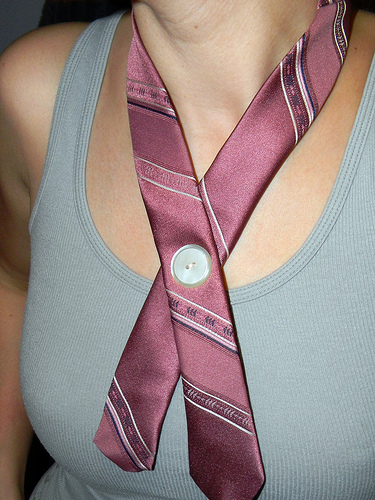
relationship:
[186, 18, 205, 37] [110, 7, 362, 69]
freckle on neck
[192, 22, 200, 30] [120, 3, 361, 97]
freckle on neck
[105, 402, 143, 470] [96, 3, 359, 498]
blue stripe on tie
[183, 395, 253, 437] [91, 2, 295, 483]
stripe on tie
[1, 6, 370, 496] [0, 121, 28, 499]
woman has arm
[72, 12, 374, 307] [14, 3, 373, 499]
stitching on tank top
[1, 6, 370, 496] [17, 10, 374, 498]
woman wearing tank top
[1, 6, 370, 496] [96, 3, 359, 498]
woman wearing tie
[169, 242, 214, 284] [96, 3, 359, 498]
button on tie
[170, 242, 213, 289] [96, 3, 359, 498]
button on tie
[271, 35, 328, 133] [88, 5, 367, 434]
stripes on tie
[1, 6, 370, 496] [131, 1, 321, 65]
woman has neck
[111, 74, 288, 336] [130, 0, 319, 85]
tie around neck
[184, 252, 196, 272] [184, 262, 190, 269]
thread in hole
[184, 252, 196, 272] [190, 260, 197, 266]
thread in hole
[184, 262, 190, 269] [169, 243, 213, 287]
hole in button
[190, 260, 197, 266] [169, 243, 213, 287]
hole in button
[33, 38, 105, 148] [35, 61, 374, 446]
strap on tank top